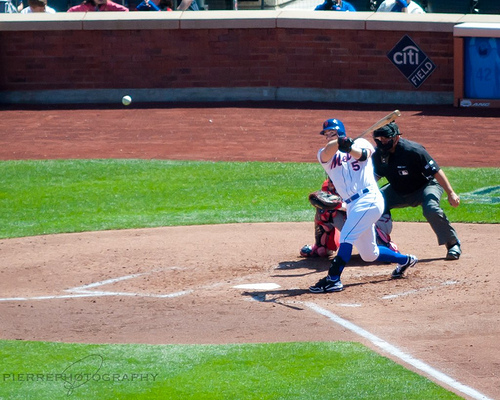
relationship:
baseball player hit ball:
[304, 115, 420, 296] [120, 91, 135, 107]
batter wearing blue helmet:
[306, 110, 416, 301] [315, 118, 345, 139]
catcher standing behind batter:
[373, 117, 462, 261] [306, 109, 416, 294]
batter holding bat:
[306, 109, 416, 294] [345, 108, 401, 141]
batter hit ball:
[306, 109, 416, 294] [121, 95, 132, 106]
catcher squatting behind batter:
[362, 117, 467, 262] [306, 110, 416, 301]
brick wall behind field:
[1, 12, 484, 103] [0, 100, 483, 390]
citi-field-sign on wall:
[385, 33, 435, 86] [30, 27, 449, 99]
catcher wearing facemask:
[373, 117, 462, 261] [372, 120, 402, 154]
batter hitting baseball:
[306, 109, 416, 294] [122, 93, 131, 106]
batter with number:
[306, 109, 416, 294] [346, 159, 362, 179]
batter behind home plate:
[306, 110, 416, 301] [230, 279, 287, 294]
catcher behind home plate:
[294, 169, 397, 270] [230, 279, 287, 294]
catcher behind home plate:
[373, 117, 462, 261] [230, 279, 287, 294]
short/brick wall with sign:
[1, 26, 450, 96] [380, 32, 438, 91]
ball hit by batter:
[121, 95, 132, 106] [306, 109, 416, 294]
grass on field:
[3, 338, 462, 397] [0, 100, 483, 390]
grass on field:
[2, 155, 481, 254] [0, 100, 483, 390]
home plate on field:
[228, 279, 287, 297] [0, 100, 483, 390]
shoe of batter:
[305, 270, 349, 297] [306, 109, 416, 294]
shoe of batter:
[387, 254, 419, 284] [306, 109, 416, 294]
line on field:
[1, 268, 205, 313] [0, 100, 483, 390]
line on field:
[301, 295, 484, 397] [0, 100, 483, 390]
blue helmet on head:
[320, 118, 347, 139] [319, 116, 346, 149]